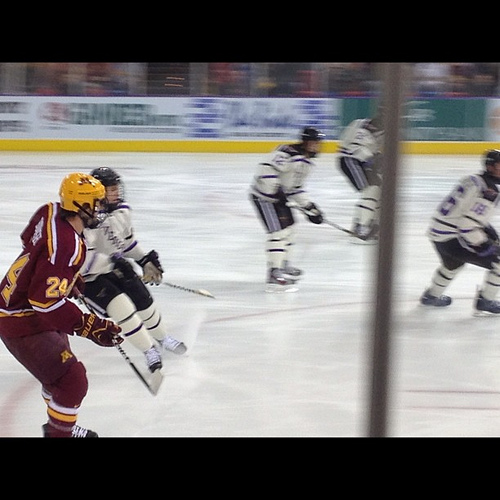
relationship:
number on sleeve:
[43, 271, 74, 304] [54, 304, 98, 331]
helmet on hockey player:
[55, 160, 106, 218] [13, 156, 112, 489]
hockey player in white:
[249, 128, 313, 278] [287, 166, 304, 189]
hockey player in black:
[13, 156, 112, 489] [289, 140, 303, 157]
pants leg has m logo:
[37, 337, 86, 390] [54, 350, 79, 364]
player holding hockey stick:
[413, 147, 499, 326] [303, 202, 379, 256]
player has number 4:
[413, 147, 499, 326] [2, 248, 33, 306]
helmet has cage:
[55, 160, 106, 218] [87, 203, 103, 225]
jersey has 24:
[43, 249, 92, 274] [43, 271, 74, 304]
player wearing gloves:
[413, 147, 499, 326] [296, 203, 330, 225]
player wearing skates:
[413, 147, 499, 326] [413, 288, 500, 320]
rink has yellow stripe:
[160, 167, 233, 215] [114, 134, 254, 152]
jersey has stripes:
[43, 249, 92, 274] [267, 240, 286, 250]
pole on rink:
[365, 65, 406, 497] [160, 167, 233, 215]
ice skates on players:
[135, 330, 196, 381] [243, 84, 498, 326]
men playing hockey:
[0, 103, 498, 441] [167, 213, 376, 339]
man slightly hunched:
[224, 123, 333, 298] [254, 164, 297, 204]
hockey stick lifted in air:
[303, 202, 379, 256] [337, 71, 379, 89]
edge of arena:
[212, 425, 279, 441] [41, 86, 497, 465]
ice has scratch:
[239, 363, 329, 403] [298, 295, 370, 321]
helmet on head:
[55, 160, 106, 218] [70, 176, 116, 197]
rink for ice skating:
[160, 167, 233, 215] [187, 245, 345, 332]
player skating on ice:
[413, 147, 499, 326] [239, 363, 329, 403]